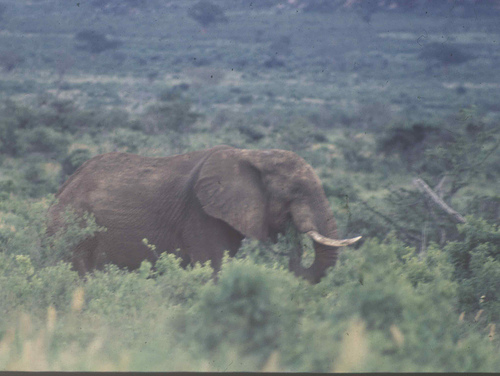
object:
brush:
[0, 0, 497, 373]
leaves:
[278, 222, 292, 252]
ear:
[194, 150, 270, 243]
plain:
[0, 0, 500, 374]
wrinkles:
[123, 181, 191, 242]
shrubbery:
[163, 250, 357, 374]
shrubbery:
[456, 214, 499, 251]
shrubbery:
[298, 278, 409, 374]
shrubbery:
[0, 204, 108, 267]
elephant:
[40, 144, 362, 285]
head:
[193, 148, 362, 284]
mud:
[252, 150, 301, 173]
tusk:
[306, 230, 362, 247]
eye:
[286, 196, 299, 205]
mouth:
[267, 214, 293, 245]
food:
[278, 221, 300, 251]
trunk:
[288, 196, 339, 284]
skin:
[103, 188, 196, 246]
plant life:
[0, 191, 499, 374]